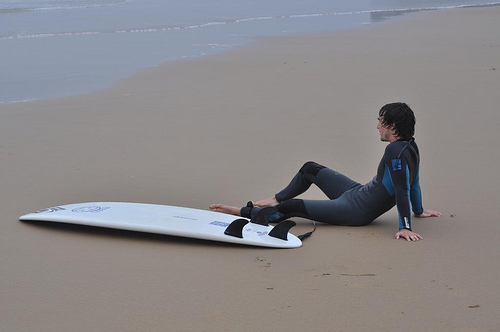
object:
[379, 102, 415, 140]
hair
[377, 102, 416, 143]
head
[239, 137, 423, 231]
wet suit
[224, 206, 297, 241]
black tether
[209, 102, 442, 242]
man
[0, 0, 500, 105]
sea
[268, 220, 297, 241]
fins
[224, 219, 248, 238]
fins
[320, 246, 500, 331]
ground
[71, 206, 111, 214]
logo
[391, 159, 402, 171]
blue patch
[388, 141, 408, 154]
shoulder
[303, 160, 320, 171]
knee(knew)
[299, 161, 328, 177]
patch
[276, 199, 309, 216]
patch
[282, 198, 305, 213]
knee(knew)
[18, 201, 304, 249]
board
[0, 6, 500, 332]
sand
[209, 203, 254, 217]
feet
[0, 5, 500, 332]
beach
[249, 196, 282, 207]
foot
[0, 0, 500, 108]
water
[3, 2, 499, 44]
waves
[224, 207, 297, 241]
skegs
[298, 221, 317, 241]
cord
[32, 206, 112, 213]
marking